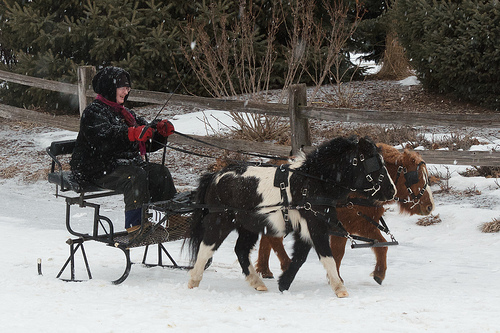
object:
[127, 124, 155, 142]
gloves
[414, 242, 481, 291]
snow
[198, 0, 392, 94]
tree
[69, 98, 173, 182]
coat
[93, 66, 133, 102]
hat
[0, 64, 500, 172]
fence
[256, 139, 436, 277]
horse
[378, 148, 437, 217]
head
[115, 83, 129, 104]
face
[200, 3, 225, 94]
branch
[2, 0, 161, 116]
trees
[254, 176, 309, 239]
spot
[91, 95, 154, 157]
scarf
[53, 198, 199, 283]
sled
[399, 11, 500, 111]
fern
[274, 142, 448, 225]
pony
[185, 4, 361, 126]
scrubs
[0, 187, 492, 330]
road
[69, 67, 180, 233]
person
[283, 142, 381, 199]
bridle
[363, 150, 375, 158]
eye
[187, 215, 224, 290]
leg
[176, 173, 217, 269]
tail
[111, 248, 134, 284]
blades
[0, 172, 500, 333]
ground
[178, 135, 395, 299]
horse